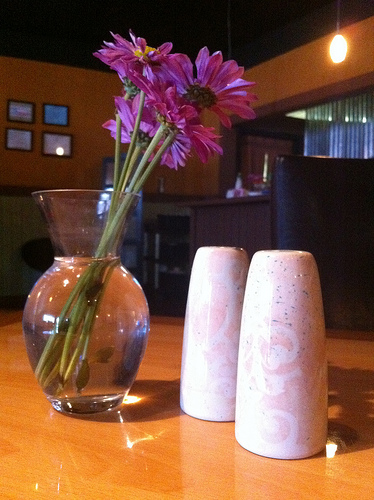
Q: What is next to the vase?
A: Salt and pepper shakers.